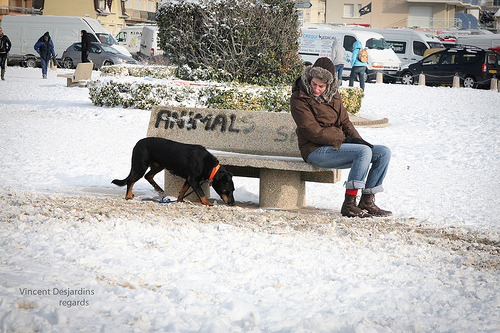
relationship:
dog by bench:
[110, 134, 238, 210] [144, 99, 341, 211]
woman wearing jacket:
[286, 56, 394, 221] [289, 57, 377, 161]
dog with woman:
[110, 134, 238, 210] [286, 56, 394, 221]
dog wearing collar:
[110, 134, 238, 210] [208, 159, 222, 185]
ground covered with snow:
[1, 64, 499, 332] [391, 91, 498, 201]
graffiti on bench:
[153, 108, 256, 135] [144, 99, 341, 211]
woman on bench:
[286, 56, 394, 221] [144, 99, 341, 211]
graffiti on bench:
[153, 108, 262, 135] [144, 99, 341, 211]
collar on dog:
[208, 159, 222, 185] [110, 134, 238, 210]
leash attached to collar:
[139, 178, 208, 204] [208, 159, 222, 185]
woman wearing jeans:
[286, 56, 394, 221] [306, 137, 391, 195]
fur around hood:
[300, 63, 340, 101] [290, 53, 343, 103]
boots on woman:
[338, 191, 394, 221] [286, 56, 394, 221]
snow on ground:
[391, 91, 498, 201] [1, 64, 499, 332]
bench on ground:
[144, 99, 341, 211] [1, 64, 499, 332]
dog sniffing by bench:
[110, 134, 238, 210] [144, 99, 341, 211]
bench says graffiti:
[144, 99, 341, 211] [153, 108, 262, 135]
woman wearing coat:
[349, 37, 368, 91] [350, 42, 369, 67]